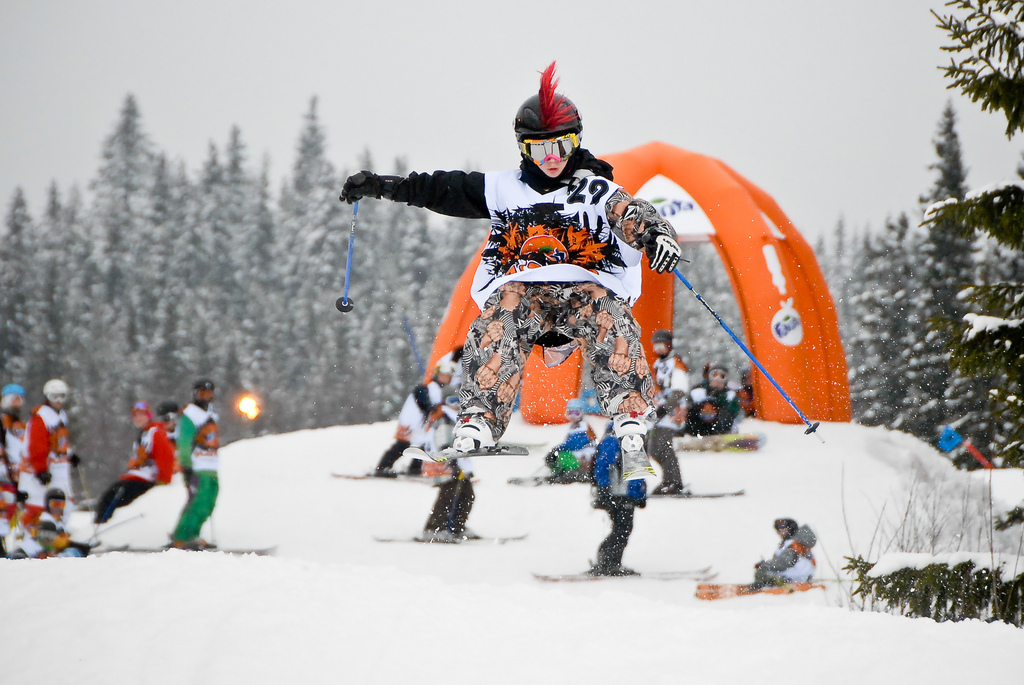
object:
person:
[740, 518, 817, 592]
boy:
[338, 94, 682, 482]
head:
[513, 93, 584, 178]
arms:
[339, 170, 682, 274]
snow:
[0, 91, 1024, 514]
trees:
[0, 0, 1024, 628]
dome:
[422, 141, 851, 425]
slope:
[66, 409, 1024, 571]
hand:
[646, 232, 683, 275]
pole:
[674, 268, 826, 444]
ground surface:
[0, 409, 1024, 684]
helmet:
[537, 60, 580, 131]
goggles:
[518, 129, 584, 166]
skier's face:
[518, 130, 583, 178]